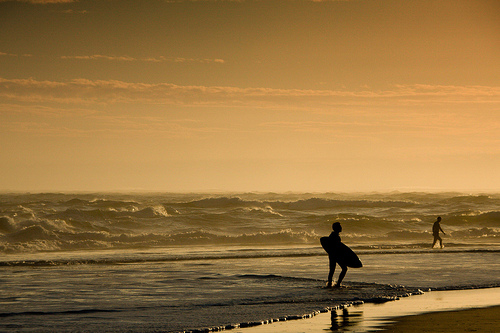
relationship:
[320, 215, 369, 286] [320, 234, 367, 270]
man carrying board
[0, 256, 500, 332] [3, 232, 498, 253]
shore by water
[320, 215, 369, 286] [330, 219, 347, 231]
man has head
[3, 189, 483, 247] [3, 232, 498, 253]
wave on water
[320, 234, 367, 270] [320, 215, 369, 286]
board held by man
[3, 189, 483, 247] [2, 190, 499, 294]
wave inside sea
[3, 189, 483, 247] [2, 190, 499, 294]
wave in sea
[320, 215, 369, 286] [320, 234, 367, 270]
man holding board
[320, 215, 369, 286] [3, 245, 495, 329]
man walking on beach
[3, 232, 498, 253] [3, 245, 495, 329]
water washing on beach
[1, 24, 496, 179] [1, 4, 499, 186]
clouds are in sky